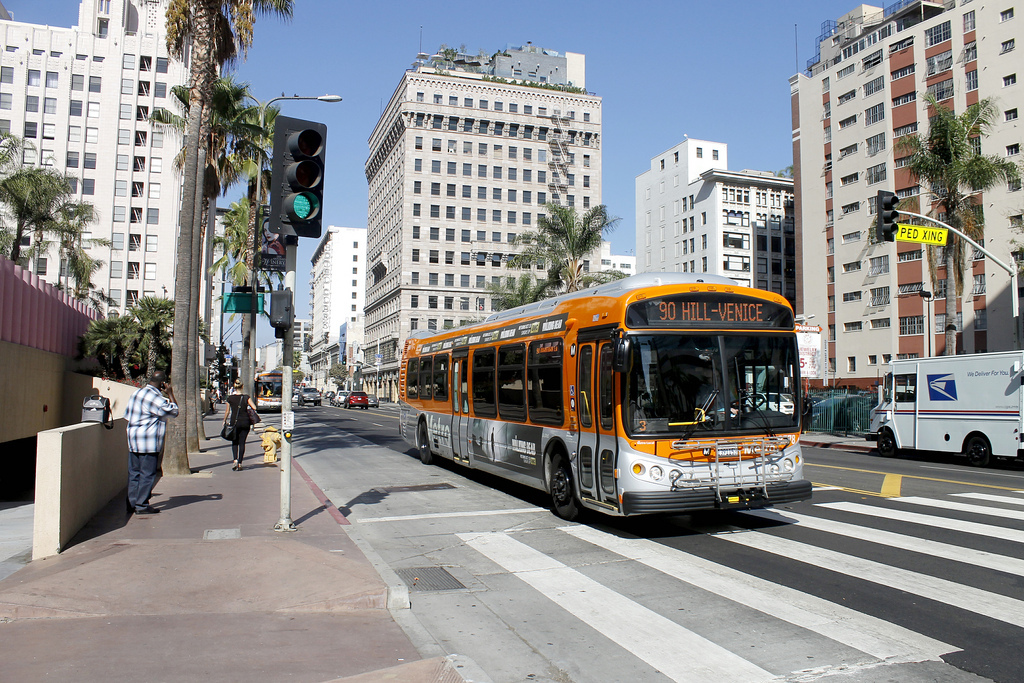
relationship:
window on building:
[577, 128, 597, 154] [359, 39, 608, 409]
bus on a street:
[400, 275, 815, 528] [253, 394, 1020, 678]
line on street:
[456, 526, 772, 678] [250, 377, 1020, 682]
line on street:
[558, 521, 956, 664] [250, 377, 1020, 682]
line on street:
[712, 521, 1022, 619] [250, 377, 1020, 682]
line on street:
[824, 495, 1023, 543] [250, 377, 1020, 682]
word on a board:
[675, 297, 714, 323] [621, 281, 794, 329]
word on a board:
[714, 299, 767, 325] [621, 281, 794, 329]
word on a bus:
[675, 297, 714, 323] [400, 275, 815, 528]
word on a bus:
[714, 299, 767, 325] [400, 275, 815, 528]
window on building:
[580, 154, 593, 172] [359, 39, 608, 409]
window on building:
[394, 229, 401, 251] [359, 39, 608, 409]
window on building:
[111, 236, 124, 254] [5, 2, 222, 372]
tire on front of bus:
[545, 443, 580, 521] [400, 275, 815, 528]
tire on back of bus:
[413, 415, 431, 452] [400, 275, 815, 528]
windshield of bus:
[617, 331, 803, 435] [400, 275, 815, 528]